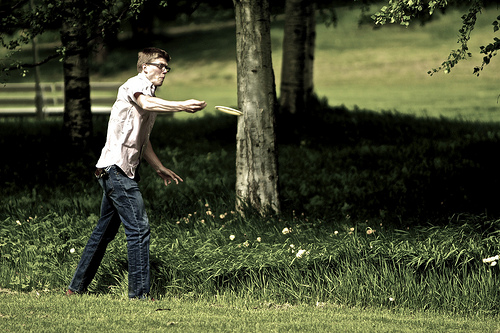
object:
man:
[57, 46, 207, 301]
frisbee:
[206, 105, 243, 115]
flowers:
[279, 226, 291, 234]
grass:
[389, 264, 446, 312]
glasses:
[140, 62, 169, 72]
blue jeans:
[66, 163, 150, 295]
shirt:
[92, 70, 166, 182]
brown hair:
[137, 50, 171, 74]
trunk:
[232, 0, 280, 221]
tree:
[0, 0, 144, 195]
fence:
[6, 74, 42, 116]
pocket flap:
[96, 167, 110, 192]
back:
[72, 156, 92, 184]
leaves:
[394, 16, 406, 28]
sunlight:
[367, 23, 410, 63]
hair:
[135, 48, 173, 73]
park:
[0, 0, 499, 333]